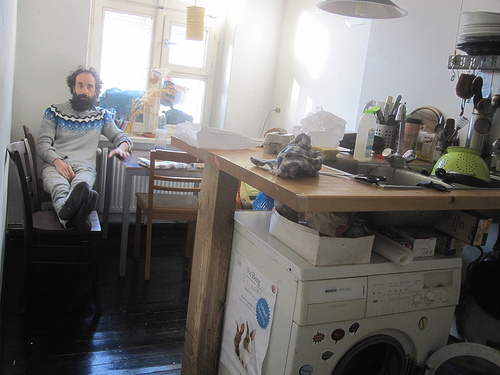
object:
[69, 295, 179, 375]
reflection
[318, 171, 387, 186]
scissors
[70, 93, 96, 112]
beard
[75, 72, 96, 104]
face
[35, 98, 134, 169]
sweater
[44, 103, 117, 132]
design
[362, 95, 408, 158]
utensils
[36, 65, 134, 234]
man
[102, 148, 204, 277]
table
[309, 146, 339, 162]
sponge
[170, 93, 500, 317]
table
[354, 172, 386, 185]
handles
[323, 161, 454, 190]
sink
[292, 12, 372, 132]
reflection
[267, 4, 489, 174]
wall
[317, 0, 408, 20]
light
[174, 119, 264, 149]
plastic bag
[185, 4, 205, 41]
light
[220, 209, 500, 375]
washer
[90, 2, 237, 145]
window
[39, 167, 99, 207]
legs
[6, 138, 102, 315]
chair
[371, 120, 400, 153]
container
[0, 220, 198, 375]
floor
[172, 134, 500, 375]
counter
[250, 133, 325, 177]
cloth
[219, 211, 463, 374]
laundry machine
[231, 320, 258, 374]
picture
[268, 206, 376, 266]
box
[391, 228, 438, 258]
box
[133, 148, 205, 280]
chair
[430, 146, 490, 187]
utensils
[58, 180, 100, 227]
feet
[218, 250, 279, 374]
paper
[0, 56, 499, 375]
kitchen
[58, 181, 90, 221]
sock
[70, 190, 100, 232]
sock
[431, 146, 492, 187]
colander